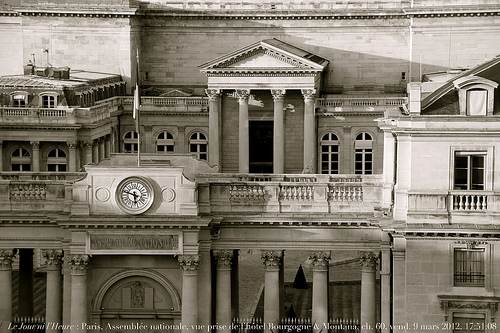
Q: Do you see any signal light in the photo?
A: No, there are no traffic lights.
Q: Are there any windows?
A: Yes, there is a window.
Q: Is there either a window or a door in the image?
A: Yes, there is a window.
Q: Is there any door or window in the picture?
A: Yes, there is a window.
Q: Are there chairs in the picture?
A: No, there are no chairs.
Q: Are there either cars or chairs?
A: No, there are no chairs or cars.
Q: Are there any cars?
A: No, there are no cars.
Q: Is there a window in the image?
A: Yes, there is a window.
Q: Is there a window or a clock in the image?
A: Yes, there is a window.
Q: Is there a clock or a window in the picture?
A: Yes, there is a window.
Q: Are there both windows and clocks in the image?
A: Yes, there are both a window and a clock.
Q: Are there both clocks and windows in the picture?
A: Yes, there are both a window and a clock.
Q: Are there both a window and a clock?
A: Yes, there are both a window and a clock.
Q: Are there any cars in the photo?
A: No, there are no cars.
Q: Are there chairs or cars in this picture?
A: No, there are no cars or chairs.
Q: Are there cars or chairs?
A: No, there are no cars or chairs.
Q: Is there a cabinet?
A: No, there are no cabinets.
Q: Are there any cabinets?
A: No, there are no cabinets.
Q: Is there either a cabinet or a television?
A: No, there are no cabinets or televisions.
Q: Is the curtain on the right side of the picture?
A: Yes, the curtain is on the right of the image.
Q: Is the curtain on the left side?
A: No, the curtain is on the right of the image.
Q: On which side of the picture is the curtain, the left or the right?
A: The curtain is on the right of the image.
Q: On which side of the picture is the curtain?
A: The curtain is on the right of the image.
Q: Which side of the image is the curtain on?
A: The curtain is on the right of the image.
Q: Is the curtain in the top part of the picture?
A: Yes, the curtain is in the top of the image.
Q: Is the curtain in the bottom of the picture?
A: No, the curtain is in the top of the image.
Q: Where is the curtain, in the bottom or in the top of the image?
A: The curtain is in the top of the image.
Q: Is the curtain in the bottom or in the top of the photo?
A: The curtain is in the top of the image.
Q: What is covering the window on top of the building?
A: The curtain is covering the window.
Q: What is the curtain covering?
A: The curtain is covering the window.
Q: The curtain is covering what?
A: The curtain is covering the window.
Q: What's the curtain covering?
A: The curtain is covering the window.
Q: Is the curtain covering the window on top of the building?
A: Yes, the curtain is covering the window.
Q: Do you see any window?
A: Yes, there is a window.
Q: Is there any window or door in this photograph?
A: Yes, there is a window.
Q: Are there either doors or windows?
A: Yes, there is a window.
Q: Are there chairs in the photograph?
A: No, there are no chairs.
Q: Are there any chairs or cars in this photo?
A: No, there are no chairs or cars.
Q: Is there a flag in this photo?
A: Yes, there is a flag.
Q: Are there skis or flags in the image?
A: Yes, there is a flag.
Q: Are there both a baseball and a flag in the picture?
A: No, there is a flag but no baseballs.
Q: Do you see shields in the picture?
A: No, there are no shields.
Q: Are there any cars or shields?
A: No, there are no shields or cars.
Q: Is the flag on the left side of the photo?
A: Yes, the flag is on the left of the image.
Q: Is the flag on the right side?
A: No, the flag is on the left of the image.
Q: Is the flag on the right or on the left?
A: The flag is on the left of the image.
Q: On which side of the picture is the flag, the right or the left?
A: The flag is on the left of the image.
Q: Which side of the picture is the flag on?
A: The flag is on the left of the image.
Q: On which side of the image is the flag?
A: The flag is on the left of the image.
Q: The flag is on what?
A: The flag is on the building.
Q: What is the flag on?
A: The flag is on the building.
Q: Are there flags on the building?
A: Yes, there is a flag on the building.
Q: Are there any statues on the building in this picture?
A: No, there is a flag on the building.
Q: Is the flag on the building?
A: Yes, the flag is on the building.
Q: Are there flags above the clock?
A: Yes, there is a flag above the clock.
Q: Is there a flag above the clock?
A: Yes, there is a flag above the clock.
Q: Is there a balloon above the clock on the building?
A: No, there is a flag above the clock.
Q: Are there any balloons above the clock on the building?
A: No, there is a flag above the clock.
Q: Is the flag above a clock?
A: Yes, the flag is above a clock.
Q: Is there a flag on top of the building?
A: Yes, there is a flag on top of the building.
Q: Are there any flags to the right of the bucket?
A: Yes, there is a flag to the right of the bucket.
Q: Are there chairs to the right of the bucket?
A: No, there is a flag to the right of the bucket.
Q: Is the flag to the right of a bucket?
A: Yes, the flag is to the right of a bucket.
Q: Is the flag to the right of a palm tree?
A: No, the flag is to the right of a bucket.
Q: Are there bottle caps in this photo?
A: No, there are no bottle caps.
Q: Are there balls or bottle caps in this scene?
A: No, there are no bottle caps or balls.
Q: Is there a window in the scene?
A: Yes, there is a window.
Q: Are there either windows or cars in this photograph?
A: Yes, there is a window.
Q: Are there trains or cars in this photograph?
A: No, there are no cars or trains.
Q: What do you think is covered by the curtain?
A: The window is covered by the curtain.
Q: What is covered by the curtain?
A: The window is covered by the curtain.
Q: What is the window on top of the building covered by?
A: The window is covered by the curtain.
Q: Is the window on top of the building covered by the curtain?
A: Yes, the window is covered by the curtain.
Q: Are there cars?
A: No, there are no cars.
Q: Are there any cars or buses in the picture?
A: No, there are no cars or buses.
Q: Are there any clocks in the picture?
A: Yes, there is a clock.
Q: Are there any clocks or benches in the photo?
A: Yes, there is a clock.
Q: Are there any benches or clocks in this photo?
A: Yes, there is a clock.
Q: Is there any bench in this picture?
A: No, there are no benches.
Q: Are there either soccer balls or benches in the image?
A: No, there are no benches or soccer balls.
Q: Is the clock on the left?
A: Yes, the clock is on the left of the image.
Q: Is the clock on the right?
A: No, the clock is on the left of the image.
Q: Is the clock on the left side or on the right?
A: The clock is on the left of the image.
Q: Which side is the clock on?
A: The clock is on the left of the image.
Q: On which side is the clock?
A: The clock is on the left of the image.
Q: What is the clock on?
A: The clock is on the building.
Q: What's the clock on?
A: The clock is on the building.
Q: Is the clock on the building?
A: Yes, the clock is on the building.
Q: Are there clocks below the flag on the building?
A: Yes, there is a clock below the flag.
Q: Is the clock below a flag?
A: Yes, the clock is below a flag.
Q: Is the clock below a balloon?
A: No, the clock is below a flag.